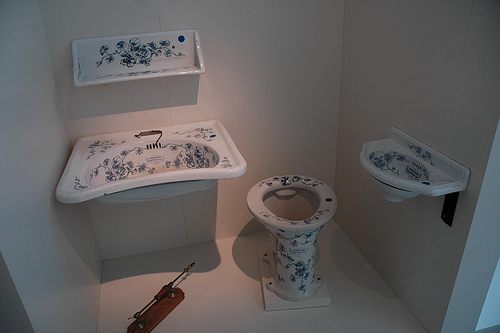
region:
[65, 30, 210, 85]
Blue flowered shelf on the wall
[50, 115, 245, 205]
Blue flowered sink.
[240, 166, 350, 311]
Blue flowered toilet.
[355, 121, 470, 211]
Small blue flowered basin.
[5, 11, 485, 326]
Bathroom with blue flowered designs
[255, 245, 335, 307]
White base under toilet.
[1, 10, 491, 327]
White bathroom walls and floor.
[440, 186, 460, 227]
Mounting bracket under basin.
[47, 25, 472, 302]
Porcelain bathroom fixtures.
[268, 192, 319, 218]
Stains visible in toilet.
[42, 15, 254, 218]
A porcelain sink and shelf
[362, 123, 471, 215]
A porcelain sink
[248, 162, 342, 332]
A porcelain toilet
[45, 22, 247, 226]
A decorative porcelain sink and shelf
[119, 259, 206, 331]
A wooden object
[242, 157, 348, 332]
A porcelain toilet lacking a back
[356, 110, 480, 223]
An ornate porcelain basin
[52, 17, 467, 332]
A decorative bathroom display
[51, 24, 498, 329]
Various decorative porcelain objects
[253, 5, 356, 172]
A white wall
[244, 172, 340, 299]
blue and white toilet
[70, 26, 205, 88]
blue and white shelf above sink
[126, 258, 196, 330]
red item on floor under sink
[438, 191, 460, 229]
black bracket holding small sink on wall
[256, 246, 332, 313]
white pedestal under toilet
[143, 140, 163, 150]
drain holes in back of sink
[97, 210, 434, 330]
white floor under toilet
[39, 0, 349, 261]
white wall behind toilet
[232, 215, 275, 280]
shadow of toilet on wall and floor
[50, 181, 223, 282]
shadow of sink underneath it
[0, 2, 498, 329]
a model of a bathroom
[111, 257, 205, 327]
wooden old fashioned tool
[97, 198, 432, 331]
white colored flooring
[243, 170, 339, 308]
blue and white porceline object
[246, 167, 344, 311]
toilet like object on the floor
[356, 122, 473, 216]
sink like object mounted to wall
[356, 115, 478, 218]
blue and white sink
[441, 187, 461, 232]
black bracket on wall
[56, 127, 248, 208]
blue and white sink on wall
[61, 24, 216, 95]
blue and white shelf on wall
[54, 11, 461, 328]
picture of small bathroom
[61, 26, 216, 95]
white shelf with blue flower pattern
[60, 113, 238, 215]
large white sink with blue flower pattern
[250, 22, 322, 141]
solid, plain white walls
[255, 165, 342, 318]
white toilet pedestal with blue flowers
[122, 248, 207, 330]
brown tool on white floor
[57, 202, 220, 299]
shadow cast under sink by light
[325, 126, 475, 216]
small white sink attached to wall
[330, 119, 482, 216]
small white sink with blue flower pattern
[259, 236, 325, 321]
white base toilet is place upon